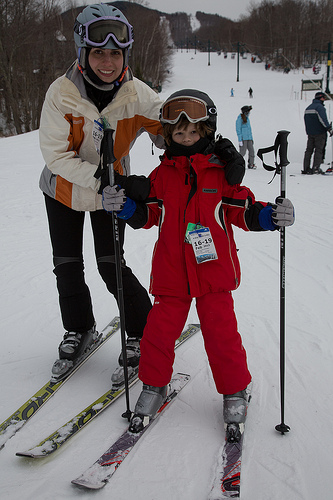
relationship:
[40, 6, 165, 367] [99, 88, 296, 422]
instructor teaching child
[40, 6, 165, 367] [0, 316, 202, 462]
instructor has skis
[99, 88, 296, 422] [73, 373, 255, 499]
child has skis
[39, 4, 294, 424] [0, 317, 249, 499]
people have skis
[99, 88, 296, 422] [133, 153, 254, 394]
child wearing snowsuit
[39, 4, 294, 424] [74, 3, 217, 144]
people wearing gear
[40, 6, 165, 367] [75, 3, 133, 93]
instructor wearing helmet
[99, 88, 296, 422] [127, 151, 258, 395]
child wearing red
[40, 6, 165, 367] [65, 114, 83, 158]
instructor wearing orange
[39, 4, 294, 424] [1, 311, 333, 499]
people in snow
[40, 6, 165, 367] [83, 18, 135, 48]
instructor has goggles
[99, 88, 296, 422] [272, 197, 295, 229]
child wearing glove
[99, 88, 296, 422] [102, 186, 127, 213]
child wearing glove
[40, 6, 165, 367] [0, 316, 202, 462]
instructor wearing skis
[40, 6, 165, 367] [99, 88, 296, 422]
instructor helping child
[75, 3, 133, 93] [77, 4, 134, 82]
helmet on head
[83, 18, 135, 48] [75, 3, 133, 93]
goggles on helmet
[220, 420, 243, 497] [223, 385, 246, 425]
ski on foot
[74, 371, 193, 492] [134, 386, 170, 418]
ski on foot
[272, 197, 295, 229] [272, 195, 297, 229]
glove on hand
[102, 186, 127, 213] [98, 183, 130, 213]
glove on hand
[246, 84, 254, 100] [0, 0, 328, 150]
skier in background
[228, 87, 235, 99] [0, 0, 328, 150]
skier in background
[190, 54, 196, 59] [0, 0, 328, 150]
skier in background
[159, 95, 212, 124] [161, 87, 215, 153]
goggles on head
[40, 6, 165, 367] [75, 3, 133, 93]
instructor with helmet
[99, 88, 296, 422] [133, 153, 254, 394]
child wearing suit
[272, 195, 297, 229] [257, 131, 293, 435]
hand holding stick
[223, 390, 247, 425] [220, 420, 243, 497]
boot lodged in ski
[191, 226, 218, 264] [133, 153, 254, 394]
tag on snowsuit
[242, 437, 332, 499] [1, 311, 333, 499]
track in snow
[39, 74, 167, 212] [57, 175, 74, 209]
jacket with accent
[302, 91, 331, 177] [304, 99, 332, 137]
man wearing coat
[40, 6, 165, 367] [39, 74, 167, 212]
instructor wearing jacket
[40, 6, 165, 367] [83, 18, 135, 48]
instructor wearing goggles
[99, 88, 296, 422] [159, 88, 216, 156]
child wearing helmet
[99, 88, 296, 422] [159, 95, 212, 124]
child wearing googles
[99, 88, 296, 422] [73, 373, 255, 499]
child on skies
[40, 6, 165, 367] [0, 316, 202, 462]
instructor on skies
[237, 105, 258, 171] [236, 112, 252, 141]
lady wearing jacket